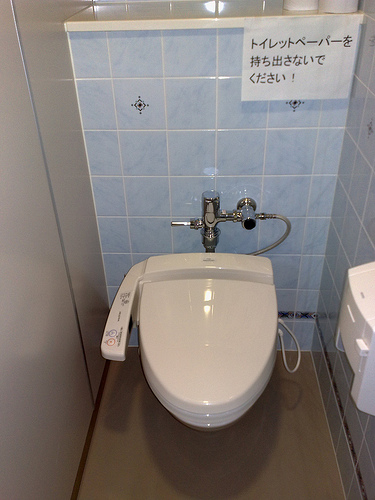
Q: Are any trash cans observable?
A: No, there are no trash cans.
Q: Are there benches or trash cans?
A: No, there are no trash cans or benches.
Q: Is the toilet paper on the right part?
A: Yes, the toilet paper is on the right of the image.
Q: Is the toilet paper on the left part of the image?
A: No, the toilet paper is on the right of the image.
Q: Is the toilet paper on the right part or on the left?
A: The toilet paper is on the right of the image.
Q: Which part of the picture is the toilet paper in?
A: The toilet paper is on the right of the image.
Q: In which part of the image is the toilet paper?
A: The toilet paper is on the right of the image.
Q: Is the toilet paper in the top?
A: Yes, the toilet paper is in the top of the image.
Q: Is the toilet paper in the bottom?
A: No, the toilet paper is in the top of the image.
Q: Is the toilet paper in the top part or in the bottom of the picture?
A: The toilet paper is in the top of the image.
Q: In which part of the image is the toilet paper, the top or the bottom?
A: The toilet paper is in the top of the image.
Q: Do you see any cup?
A: No, there are no cups.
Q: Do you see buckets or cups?
A: No, there are no cups or buckets.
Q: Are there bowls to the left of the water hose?
A: Yes, there is a bowl to the left of the water hose.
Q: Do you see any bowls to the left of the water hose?
A: Yes, there is a bowl to the left of the water hose.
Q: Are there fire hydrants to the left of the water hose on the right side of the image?
A: No, there is a bowl to the left of the hose.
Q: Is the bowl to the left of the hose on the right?
A: Yes, the bowl is to the left of the hose.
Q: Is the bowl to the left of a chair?
A: No, the bowl is to the left of the hose.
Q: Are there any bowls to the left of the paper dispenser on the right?
A: Yes, there is a bowl to the left of the paper dispenser.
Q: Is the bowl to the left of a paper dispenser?
A: Yes, the bowl is to the left of a paper dispenser.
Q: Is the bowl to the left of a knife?
A: No, the bowl is to the left of a paper dispenser.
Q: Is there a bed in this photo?
A: No, there are no beds.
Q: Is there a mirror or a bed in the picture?
A: No, there are no beds or mirrors.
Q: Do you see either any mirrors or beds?
A: No, there are no beds or mirrors.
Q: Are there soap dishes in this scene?
A: No, there are no soap dishes.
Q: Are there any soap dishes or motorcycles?
A: No, there are no soap dishes or motorcycles.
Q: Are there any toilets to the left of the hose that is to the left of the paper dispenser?
A: Yes, there is a toilet to the left of the hose.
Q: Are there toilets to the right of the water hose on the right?
A: No, the toilet is to the left of the hose.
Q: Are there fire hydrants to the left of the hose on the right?
A: No, there is a toilet to the left of the water hose.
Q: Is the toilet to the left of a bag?
A: No, the toilet is to the left of the hose.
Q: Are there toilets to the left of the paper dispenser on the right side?
A: Yes, there is a toilet to the left of the paper dispenser.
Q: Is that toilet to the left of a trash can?
A: No, the toilet is to the left of a paper dispenser.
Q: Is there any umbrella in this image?
A: No, there are no umbrellas.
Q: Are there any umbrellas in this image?
A: No, there are no umbrellas.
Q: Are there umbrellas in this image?
A: No, there are no umbrellas.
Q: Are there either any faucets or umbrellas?
A: No, there are no umbrellas or faucets.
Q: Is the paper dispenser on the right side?
A: Yes, the paper dispenser is on the right of the image.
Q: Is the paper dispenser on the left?
A: No, the paper dispenser is on the right of the image.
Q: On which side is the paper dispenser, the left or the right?
A: The paper dispenser is on the right of the image.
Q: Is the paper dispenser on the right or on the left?
A: The paper dispenser is on the right of the image.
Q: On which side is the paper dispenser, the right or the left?
A: The paper dispenser is on the right of the image.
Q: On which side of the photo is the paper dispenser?
A: The paper dispenser is on the right of the image.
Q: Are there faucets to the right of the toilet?
A: No, there is a paper dispenser to the right of the toilet.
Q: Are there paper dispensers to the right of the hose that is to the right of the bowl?
A: Yes, there is a paper dispenser to the right of the hose.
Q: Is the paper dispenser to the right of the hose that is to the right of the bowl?
A: Yes, the paper dispenser is to the right of the hose.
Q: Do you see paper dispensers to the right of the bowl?
A: Yes, there is a paper dispenser to the right of the bowl.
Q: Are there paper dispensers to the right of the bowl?
A: Yes, there is a paper dispenser to the right of the bowl.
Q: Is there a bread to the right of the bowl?
A: No, there is a paper dispenser to the right of the bowl.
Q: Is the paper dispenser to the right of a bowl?
A: Yes, the paper dispenser is to the right of a bowl.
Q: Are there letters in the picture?
A: Yes, there are letters.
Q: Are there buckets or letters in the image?
A: Yes, there are letters.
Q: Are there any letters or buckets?
A: Yes, there are letters.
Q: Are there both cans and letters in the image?
A: No, there are letters but no cans.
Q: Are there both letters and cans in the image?
A: No, there are letters but no cans.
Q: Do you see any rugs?
A: No, there are no rugs.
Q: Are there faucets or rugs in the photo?
A: No, there are no rugs or faucets.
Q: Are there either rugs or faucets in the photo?
A: No, there are no rugs or faucets.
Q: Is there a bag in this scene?
A: No, there are no bags.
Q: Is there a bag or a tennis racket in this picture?
A: No, there are no bags or rackets.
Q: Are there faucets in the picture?
A: No, there are no faucets.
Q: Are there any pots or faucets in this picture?
A: No, there are no faucets or pots.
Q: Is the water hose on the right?
A: Yes, the water hose is on the right of the image.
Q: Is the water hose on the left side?
A: No, the water hose is on the right of the image.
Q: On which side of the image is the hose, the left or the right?
A: The hose is on the right of the image.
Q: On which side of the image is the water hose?
A: The water hose is on the right of the image.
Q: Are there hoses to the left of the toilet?
A: No, the hose is to the right of the toilet.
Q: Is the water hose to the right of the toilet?
A: Yes, the water hose is to the right of the toilet.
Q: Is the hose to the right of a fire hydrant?
A: No, the hose is to the right of the toilet.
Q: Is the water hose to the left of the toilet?
A: No, the water hose is to the right of the toilet.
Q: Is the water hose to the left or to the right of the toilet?
A: The water hose is to the right of the toilet.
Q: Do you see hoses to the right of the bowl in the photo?
A: Yes, there is a hose to the right of the bowl.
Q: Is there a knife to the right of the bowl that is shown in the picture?
A: No, there is a hose to the right of the bowl.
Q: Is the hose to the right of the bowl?
A: Yes, the hose is to the right of the bowl.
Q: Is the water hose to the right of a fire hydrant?
A: No, the water hose is to the right of the bowl.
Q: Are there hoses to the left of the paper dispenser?
A: Yes, there is a hose to the left of the paper dispenser.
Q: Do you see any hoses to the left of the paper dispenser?
A: Yes, there is a hose to the left of the paper dispenser.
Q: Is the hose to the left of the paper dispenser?
A: Yes, the hose is to the left of the paper dispenser.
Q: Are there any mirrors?
A: No, there are no mirrors.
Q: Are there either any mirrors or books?
A: No, there are no mirrors or books.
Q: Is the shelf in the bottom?
A: No, the shelf is in the top of the image.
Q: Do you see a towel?
A: No, there are no towels.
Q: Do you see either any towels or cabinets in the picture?
A: No, there are no towels or cabinets.